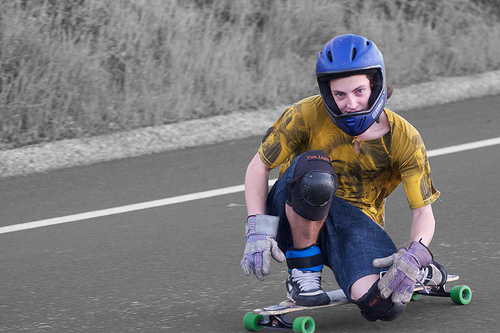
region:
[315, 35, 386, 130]
purple helmet on skateboarders' head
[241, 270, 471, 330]
green and white skateboard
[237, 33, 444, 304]
young boy on a skateboard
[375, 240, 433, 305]
left glove on skateboarders' hand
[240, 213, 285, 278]
glove on the right hand of the skateboarder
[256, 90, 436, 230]
gold and black colored tee shirt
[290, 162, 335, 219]
skateboarders' black knee pad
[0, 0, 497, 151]
weeds in the background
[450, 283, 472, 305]
left rear wheel of the skateboard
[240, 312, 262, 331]
right front wheel of the skateboard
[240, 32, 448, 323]
Man skateboarding on the road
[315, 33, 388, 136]
Helmet on the man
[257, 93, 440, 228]
Shirt on the man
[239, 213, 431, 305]
Gloves on the man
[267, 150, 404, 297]
Shorts on the man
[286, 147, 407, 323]
Knee pads on the man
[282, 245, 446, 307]
Shoes on the man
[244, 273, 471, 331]
Skateboard under the man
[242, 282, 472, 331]
Wheels of the skateboard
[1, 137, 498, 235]
White line on the road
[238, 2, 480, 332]
the man croutching on the board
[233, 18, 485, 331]
the skateboarder rides down the hill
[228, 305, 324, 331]
the green front wheels of the baord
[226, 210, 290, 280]
a gardening golve on the hand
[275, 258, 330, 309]
the show on the skateboard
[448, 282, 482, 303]
the green wheel on the pavement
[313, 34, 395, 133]
the blue helmet on the mans head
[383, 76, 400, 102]
the hair sticking out from the helmet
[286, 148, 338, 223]
the kneepad on the mans knee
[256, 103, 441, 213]
the yellow tee shirt on the man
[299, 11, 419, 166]
the helmet is blue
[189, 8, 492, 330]
boy is riding a skateboard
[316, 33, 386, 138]
blue helmet over a skater's head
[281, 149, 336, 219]
black knee pad on a skater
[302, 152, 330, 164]
red print on a knee pad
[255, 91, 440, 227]
yellow and black shirt on a skater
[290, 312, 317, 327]
green wheel of a skateboard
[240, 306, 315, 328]
front wheels of a skateboard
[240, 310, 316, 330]
two green skateboard wheels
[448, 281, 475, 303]
back green wheel of a skateboard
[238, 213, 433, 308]
gloves on a skateboarders hands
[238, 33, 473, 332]
young man on a skateboard